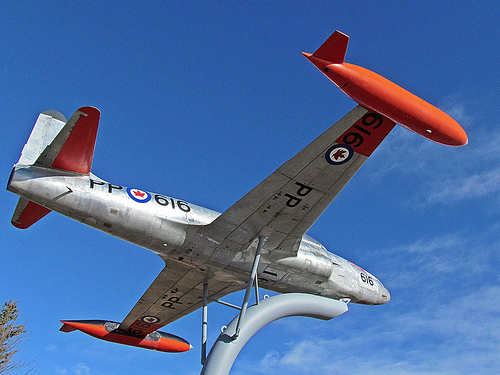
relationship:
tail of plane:
[17, 124, 57, 204] [159, 210, 261, 274]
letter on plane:
[300, 181, 306, 194] [159, 210, 261, 274]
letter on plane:
[285, 195, 297, 206] [159, 210, 261, 274]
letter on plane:
[174, 296, 180, 305] [159, 210, 261, 274]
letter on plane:
[165, 300, 169, 308] [159, 210, 261, 274]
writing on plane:
[103, 185, 183, 214] [159, 210, 261, 274]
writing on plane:
[330, 124, 384, 168] [159, 210, 261, 274]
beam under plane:
[262, 307, 320, 311] [159, 210, 261, 274]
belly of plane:
[97, 211, 158, 236] [159, 210, 261, 274]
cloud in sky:
[440, 179, 475, 199] [119, 17, 263, 83]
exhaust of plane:
[10, 171, 13, 186] [159, 210, 261, 274]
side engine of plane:
[351, 76, 425, 119] [159, 210, 261, 274]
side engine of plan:
[94, 327, 123, 336] [188, 239, 241, 274]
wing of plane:
[263, 181, 283, 242] [159, 210, 261, 274]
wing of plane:
[169, 272, 200, 290] [159, 210, 261, 274]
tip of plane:
[389, 296, 393, 302] [159, 210, 261, 274]